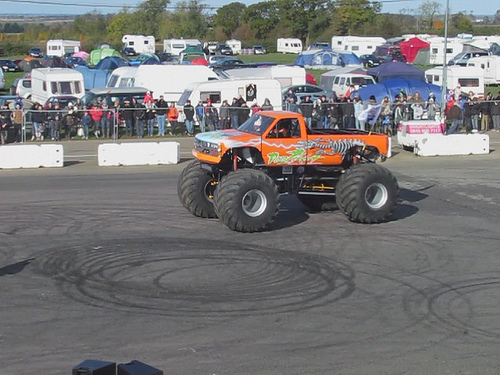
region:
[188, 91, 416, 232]
An orange monster truck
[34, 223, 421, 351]
Circular tracks in the dirt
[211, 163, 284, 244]
Large black tires on a monster truck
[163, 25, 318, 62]
Campers in a field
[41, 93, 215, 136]
Spectators standing at a railing watching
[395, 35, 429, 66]
A red tent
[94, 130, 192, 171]
A white barricade protecting spectators from a monster truck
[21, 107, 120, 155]
A fence keeping spectators out of a monster truck arena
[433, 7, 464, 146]
A tall pole sticking up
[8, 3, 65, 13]
A light blue sky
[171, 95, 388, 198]
Orange monster truck on cement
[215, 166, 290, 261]
Large tire on a monster truck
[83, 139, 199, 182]
White cement block by a track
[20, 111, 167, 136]
Fence by a track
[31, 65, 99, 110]
White travel trailer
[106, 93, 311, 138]
Crowd standing by a track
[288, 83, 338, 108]
Silver car by a track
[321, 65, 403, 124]
White van in a parking lot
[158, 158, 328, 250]
Tires on a monster truck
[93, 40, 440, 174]
Parking lot full of travel trailers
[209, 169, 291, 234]
a large black tire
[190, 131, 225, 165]
the grill of the truck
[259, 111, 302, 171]
the door of the truck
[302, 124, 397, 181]
the bed of the truck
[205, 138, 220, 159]
the headlight of the truck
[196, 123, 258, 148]
the hood of the truck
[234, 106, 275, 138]
the windshield of the truck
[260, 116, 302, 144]
the driver's window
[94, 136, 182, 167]
a white cement barrier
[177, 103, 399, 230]
The orange monster truck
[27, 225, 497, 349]
The circular tire marks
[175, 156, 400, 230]
The tires of the truck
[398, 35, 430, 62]
The large red tent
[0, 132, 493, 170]
The white barricades behind the truck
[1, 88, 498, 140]
The spectators behind the fence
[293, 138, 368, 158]
The skeleton on the side of the truck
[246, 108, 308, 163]
The cab of the truck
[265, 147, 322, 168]
The green writing on the truck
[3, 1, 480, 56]
The trees behind the rvs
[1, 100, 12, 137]
a person is standing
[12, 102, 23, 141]
a person is standing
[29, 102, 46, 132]
a person is standing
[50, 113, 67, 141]
a person is standing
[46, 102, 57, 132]
a person is standing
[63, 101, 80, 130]
a person is standing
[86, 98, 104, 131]
a person is standing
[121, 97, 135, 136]
a person is standing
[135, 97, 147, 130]
a person is standing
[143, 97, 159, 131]
a person is standing